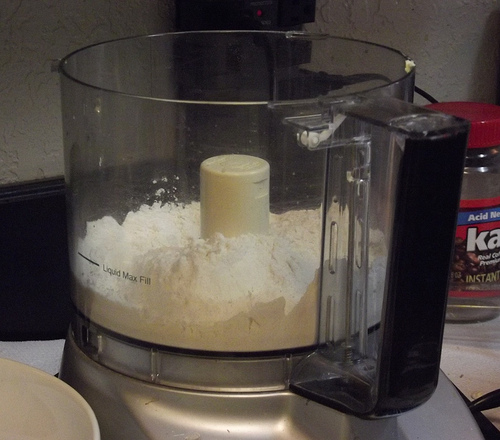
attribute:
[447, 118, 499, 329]
label — red, blue, white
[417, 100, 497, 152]
top — red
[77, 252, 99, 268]
mark — black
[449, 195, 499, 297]
label — red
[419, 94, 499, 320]
jar — empty, glass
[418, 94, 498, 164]
lid — round, red, jar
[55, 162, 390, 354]
flour — white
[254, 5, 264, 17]
light — red, unlit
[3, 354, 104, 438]
dish — white, round, ceramic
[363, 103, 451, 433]
handle — black, plastic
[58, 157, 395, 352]
powder — white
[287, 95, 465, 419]
handle — black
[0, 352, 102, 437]
bowl — cream colored, ivory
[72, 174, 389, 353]
flour — white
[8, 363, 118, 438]
mug — white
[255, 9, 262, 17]
button — round, red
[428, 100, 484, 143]
top — red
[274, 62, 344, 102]
plug — black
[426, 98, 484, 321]
bottle — karo syrup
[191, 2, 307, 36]
surface — black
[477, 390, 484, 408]
cording — black, electric